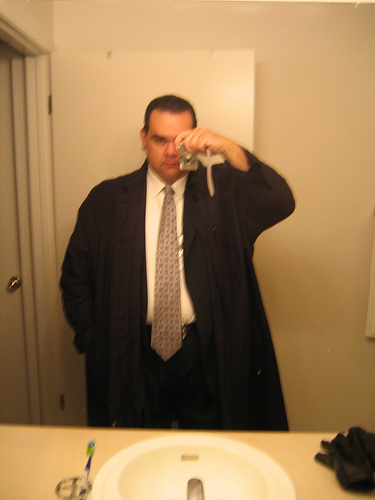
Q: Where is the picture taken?
A: A bathroom.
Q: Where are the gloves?
A: The counter.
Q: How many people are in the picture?
A: One.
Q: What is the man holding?
A: A camera.